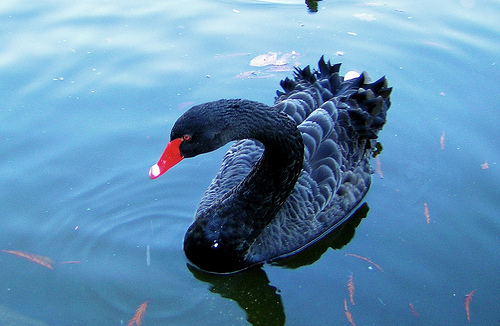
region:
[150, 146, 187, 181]
The red duck beak.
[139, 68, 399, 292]
The duck in the water.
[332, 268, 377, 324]
The leaves in the water.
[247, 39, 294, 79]
The debris in the water.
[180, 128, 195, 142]
The duck eye.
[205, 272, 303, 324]
The duck shadow.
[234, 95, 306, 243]
The neck of the duck.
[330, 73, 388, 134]
The duck feathers.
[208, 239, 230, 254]
The white debris on the duck.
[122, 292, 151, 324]
An orange fish in the water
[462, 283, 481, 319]
An orange fish in the water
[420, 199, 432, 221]
An orange fish in the water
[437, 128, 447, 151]
An orange fish in the water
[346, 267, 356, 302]
An orange fish in the water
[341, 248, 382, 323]
Three orange fishes in the water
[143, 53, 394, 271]
A goose on the water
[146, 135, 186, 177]
A goose's red bill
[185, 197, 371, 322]
The shadow of a goose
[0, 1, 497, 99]
Reflection of clouds on the water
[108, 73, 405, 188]
black bird in water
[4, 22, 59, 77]
white and blue lake wves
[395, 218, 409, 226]
white and blue lake wves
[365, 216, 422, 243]
white and blue lake wves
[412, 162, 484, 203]
white and blue lake wves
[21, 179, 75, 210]
white and blue lake wves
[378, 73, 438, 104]
white and blue lake wves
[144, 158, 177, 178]
Duck has red beak.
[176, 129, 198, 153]
Duck has red eye.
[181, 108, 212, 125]
Duck has black head.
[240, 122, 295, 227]
Duck has long neck.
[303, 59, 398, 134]
Duck has black and gray tail feathers.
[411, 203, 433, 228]
Leaf floating in water.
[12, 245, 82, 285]
Leaf floating in water.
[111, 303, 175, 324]
Leaf floating in water.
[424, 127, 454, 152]
Leaf floating in water.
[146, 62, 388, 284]
black swan on a lake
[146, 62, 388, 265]
black feathered swan on a lake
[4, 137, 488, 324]
little pinky fishes on a lake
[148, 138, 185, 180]
large red and white peak of swan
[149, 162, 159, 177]
white part in the peak of swan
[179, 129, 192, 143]
small black and red left eye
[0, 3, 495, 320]
light blue and calm lake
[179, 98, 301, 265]
black feathers on large neck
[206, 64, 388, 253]
black and gray feathers on big body of swan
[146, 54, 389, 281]
black swan surrounded by pink fishes